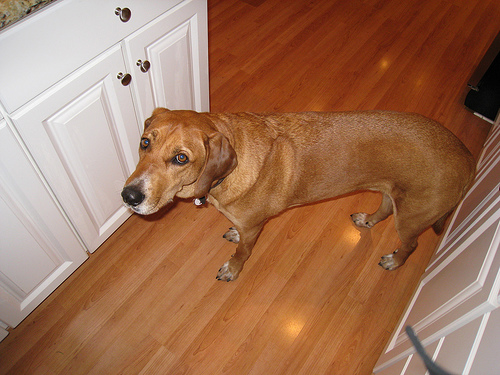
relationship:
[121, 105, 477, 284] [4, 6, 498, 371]
dog between cabinets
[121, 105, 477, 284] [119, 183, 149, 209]
dog has nose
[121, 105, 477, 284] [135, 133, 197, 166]
dog has eyes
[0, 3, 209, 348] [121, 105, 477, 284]
cabinet in front of dog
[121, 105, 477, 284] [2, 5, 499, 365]
dog on floor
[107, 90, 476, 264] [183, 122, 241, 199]
dog has ear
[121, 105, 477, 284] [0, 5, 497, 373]
dog standing in kitchen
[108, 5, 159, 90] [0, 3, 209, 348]
knobs of cabinet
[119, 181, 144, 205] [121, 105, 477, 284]
nose of dog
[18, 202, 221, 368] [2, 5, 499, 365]
panels on floor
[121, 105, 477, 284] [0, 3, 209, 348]
dog next to cabinet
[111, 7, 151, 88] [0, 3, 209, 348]
knobs on cabinet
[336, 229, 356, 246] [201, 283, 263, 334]
light on floor